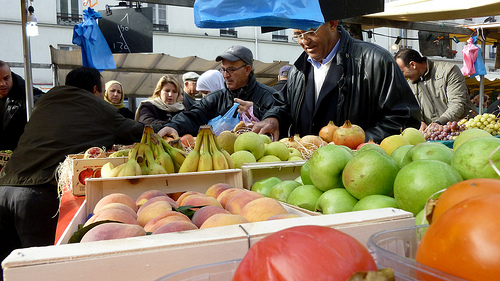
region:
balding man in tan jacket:
[392, 47, 471, 130]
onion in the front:
[332, 118, 366, 148]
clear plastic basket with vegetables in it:
[366, 222, 463, 279]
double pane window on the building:
[56, 0, 82, 23]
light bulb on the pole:
[24, 14, 38, 37]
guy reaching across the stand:
[1, 65, 146, 255]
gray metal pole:
[478, 34, 485, 112]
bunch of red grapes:
[423, 119, 465, 140]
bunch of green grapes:
[458, 111, 498, 133]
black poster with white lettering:
[97, 6, 153, 51]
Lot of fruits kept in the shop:
[96, 106, 496, 276]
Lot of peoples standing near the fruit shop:
[75, 18, 439, 113]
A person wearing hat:
[214, 43, 257, 67]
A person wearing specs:
[217, 64, 237, 75]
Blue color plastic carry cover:
[73, 15, 119, 69]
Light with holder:
[23, 5, 43, 40]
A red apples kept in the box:
[100, 190, 240, 224]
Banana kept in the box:
[121, 144, 227, 171]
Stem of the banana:
[191, 123, 218, 140]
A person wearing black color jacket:
[353, 45, 390, 100]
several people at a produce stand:
[7, 3, 469, 188]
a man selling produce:
[21, 68, 191, 172]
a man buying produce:
[163, 41, 279, 146]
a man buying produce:
[266, 16, 423, 145]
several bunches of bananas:
[110, 119, 235, 173]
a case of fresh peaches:
[90, 183, 293, 238]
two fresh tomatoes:
[416, 179, 498, 273]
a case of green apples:
[264, 143, 492, 210]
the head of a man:
[391, 43, 428, 85]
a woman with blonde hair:
[148, 69, 181, 108]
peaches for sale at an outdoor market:
[62, 177, 287, 254]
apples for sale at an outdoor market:
[266, 136, 493, 204]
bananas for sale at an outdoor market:
[97, 119, 233, 182]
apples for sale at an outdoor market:
[230, 127, 301, 165]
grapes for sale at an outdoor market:
[422, 113, 498, 140]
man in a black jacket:
[280, 21, 420, 128]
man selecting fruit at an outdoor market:
[159, 43, 281, 145]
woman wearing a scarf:
[136, 72, 188, 130]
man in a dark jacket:
[8, 64, 130, 194]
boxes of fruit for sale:
[80, 112, 496, 277]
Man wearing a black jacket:
[252, 14, 422, 145]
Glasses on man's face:
[288, 20, 324, 43]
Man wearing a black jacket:
[166, 48, 283, 136]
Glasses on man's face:
[215, 61, 248, 76]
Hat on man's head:
[208, 41, 253, 66]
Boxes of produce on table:
[44, 121, 499, 280]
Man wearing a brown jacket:
[0, 70, 152, 247]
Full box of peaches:
[56, 174, 303, 254]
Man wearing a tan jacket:
[387, 46, 470, 124]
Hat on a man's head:
[177, 67, 200, 83]